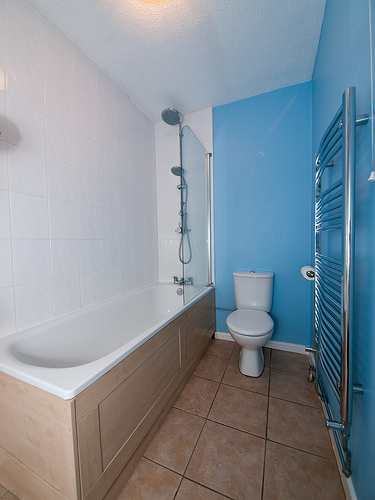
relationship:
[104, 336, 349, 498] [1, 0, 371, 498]
flooring in bathroom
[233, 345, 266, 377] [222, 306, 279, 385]
base of toilet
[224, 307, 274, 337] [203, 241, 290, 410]
seat of toilet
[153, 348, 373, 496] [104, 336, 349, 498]
tiles on flooring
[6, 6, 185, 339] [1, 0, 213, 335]
tiles on wall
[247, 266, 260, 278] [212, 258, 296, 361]
buttons on toilet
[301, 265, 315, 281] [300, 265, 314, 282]
paper of paper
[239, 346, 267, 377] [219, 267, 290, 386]
base of a toilet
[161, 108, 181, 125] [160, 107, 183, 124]
shower head of a shower head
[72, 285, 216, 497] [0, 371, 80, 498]
wood portion of a wood portion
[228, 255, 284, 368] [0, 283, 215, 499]
toilet sitting beside bath tub